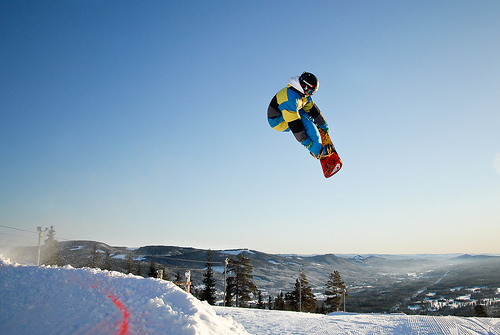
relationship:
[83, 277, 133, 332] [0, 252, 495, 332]
paint in snow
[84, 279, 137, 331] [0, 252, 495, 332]
line in snow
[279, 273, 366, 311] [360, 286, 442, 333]
pine trees along ski path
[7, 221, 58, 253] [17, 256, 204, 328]
power line above ski slope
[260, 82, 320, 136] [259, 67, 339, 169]
gear worn by person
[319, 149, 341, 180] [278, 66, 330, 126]
snowboard of athlete